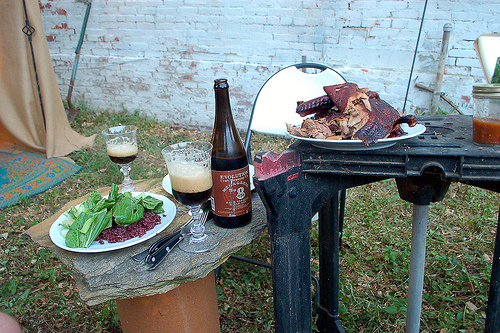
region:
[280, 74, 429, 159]
Plate topped with meat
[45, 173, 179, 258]
Plate topped with vegetables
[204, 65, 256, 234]
Brown bottle containing an alcoholic beverage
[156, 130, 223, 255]
Glass cup filled with brown alcoholic beverage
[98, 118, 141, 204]
Drinking glass filled with brown drink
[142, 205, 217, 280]
Metal eating utensils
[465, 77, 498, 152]
Jar filled with red liquid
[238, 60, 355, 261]
Black and white outdoor chair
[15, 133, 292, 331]
Makeshift slate rock table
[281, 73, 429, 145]
Ribs and other cooked meat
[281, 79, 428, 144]
A plate of ribs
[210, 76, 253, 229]
A bottle of beer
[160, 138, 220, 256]
A glass of beer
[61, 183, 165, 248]
Lettuce on a plate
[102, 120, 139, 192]
A glass of beer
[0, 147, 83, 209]
A blue and orange carpet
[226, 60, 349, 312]
A white folding chair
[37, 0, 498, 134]
A wall of white bricks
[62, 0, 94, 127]
A green and rusty shovel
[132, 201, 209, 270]
Black and silver utensils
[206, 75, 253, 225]
a brown bottle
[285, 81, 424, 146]
a plate of meat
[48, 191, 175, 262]
a round white plate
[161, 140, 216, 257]
a glass of beer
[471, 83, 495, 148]
a jar with a lid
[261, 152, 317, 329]
a black metal leg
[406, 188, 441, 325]
a white metal leg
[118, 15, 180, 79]
a white brick wall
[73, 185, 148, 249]
a green vegetable on a plate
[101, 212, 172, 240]
beans on a plate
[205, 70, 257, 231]
a bottle color brown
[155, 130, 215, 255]
a cup of beer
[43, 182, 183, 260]
vegetables on dish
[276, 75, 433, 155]
meat on a dish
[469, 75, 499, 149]
a jar of read sauce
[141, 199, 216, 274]
fork besides a dish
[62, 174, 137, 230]
green leaves on a dish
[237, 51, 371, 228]
a metal chair on the grass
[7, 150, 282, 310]
a dish over a flat stone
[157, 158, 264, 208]
a empty white dish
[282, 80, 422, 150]
A plate of barbecued meat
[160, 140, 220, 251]
A clear glass with beer in it.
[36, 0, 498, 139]
A painted brick wall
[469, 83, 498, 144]
A jar of sauce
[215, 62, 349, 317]
A metal chair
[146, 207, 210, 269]
A fork next to a glass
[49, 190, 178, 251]
A plate of greens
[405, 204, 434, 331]
A metal pole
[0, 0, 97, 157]
A beige cloth or tent